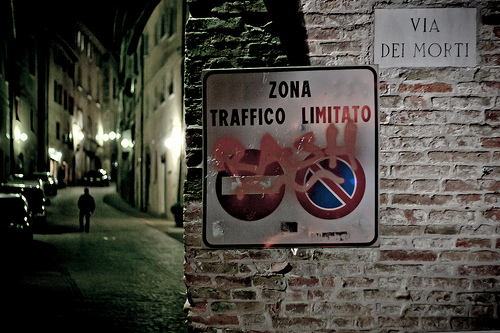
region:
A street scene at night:
[11, 22, 491, 316]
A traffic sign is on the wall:
[195, 62, 393, 259]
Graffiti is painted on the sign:
[206, 132, 372, 194]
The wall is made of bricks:
[389, 99, 491, 309]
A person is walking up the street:
[70, 182, 102, 235]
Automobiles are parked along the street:
[1, 164, 63, 238]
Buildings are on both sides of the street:
[23, 28, 180, 179]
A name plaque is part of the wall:
[369, 5, 483, 70]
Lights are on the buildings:
[96, 128, 183, 155]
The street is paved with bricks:
[78, 240, 183, 320]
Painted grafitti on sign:
[195, 113, 385, 201]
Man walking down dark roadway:
[66, 172, 101, 241]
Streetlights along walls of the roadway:
[2, 125, 139, 168]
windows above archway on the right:
[137, 60, 179, 118]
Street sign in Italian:
[366, 1, 482, 73]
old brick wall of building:
[181, 13, 496, 320]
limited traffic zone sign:
[210, 65, 376, 247]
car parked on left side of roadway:
[80, 160, 111, 190]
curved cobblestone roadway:
[5, 165, 176, 330]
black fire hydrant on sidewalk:
[171, 196, 184, 229]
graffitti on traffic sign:
[197, 103, 375, 200]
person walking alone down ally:
[64, 150, 109, 239]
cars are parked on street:
[10, 160, 67, 245]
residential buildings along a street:
[36, 17, 179, 193]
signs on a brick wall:
[187, 1, 486, 296]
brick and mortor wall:
[393, 140, 494, 312]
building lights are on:
[71, 111, 139, 156]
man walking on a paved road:
[62, 180, 127, 239]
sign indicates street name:
[362, 5, 489, 75]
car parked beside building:
[83, 157, 108, 184]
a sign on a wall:
[164, 28, 394, 291]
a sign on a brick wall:
[130, 20, 430, 288]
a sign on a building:
[182, 30, 447, 306]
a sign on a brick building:
[164, 37, 443, 317]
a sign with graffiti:
[173, 25, 393, 269]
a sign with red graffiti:
[174, 32, 421, 287]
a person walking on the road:
[57, 165, 126, 275]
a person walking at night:
[64, 174, 111, 238]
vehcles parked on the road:
[5, 161, 65, 245]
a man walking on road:
[59, 171, 111, 251]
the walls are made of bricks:
[412, 105, 475, 252]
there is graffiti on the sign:
[213, 124, 359, 179]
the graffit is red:
[213, 139, 361, 174]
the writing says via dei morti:
[372, 11, 485, 61]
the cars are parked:
[21, 165, 54, 260]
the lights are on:
[92, 125, 134, 152]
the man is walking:
[72, 185, 97, 230]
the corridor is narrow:
[45, 165, 172, 314]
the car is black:
[77, 167, 114, 189]